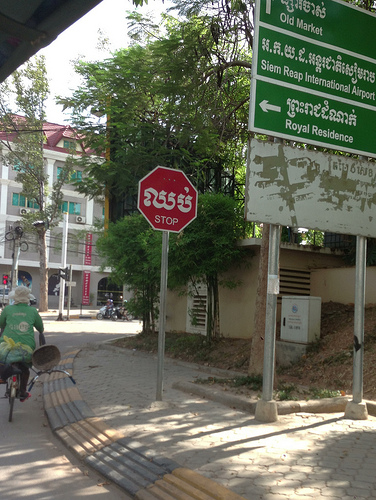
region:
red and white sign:
[119, 155, 194, 225]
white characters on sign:
[128, 167, 202, 230]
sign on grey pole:
[133, 167, 184, 403]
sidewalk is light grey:
[92, 355, 307, 485]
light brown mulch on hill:
[292, 319, 366, 399]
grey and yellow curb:
[43, 348, 201, 497]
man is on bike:
[3, 291, 41, 410]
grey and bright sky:
[29, 8, 121, 116]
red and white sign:
[130, 162, 196, 232]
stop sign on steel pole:
[150, 223, 169, 405]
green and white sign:
[242, 3, 375, 153]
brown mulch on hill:
[314, 295, 375, 382]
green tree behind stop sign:
[94, 8, 245, 305]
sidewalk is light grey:
[92, 331, 356, 493]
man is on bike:
[3, 296, 64, 384]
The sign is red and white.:
[128, 158, 202, 239]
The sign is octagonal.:
[136, 162, 200, 237]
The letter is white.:
[152, 212, 162, 225]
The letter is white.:
[159, 211, 167, 226]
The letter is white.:
[171, 215, 180, 230]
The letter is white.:
[164, 213, 173, 226]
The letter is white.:
[282, 115, 292, 130]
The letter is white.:
[309, 123, 318, 138]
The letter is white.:
[281, 59, 290, 79]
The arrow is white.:
[254, 89, 285, 118]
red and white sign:
[125, 164, 199, 238]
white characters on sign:
[138, 165, 198, 236]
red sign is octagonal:
[138, 165, 189, 233]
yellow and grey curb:
[35, 349, 198, 484]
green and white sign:
[264, 17, 375, 126]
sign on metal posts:
[268, 214, 368, 417]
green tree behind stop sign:
[88, 34, 238, 303]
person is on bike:
[1, 285, 59, 391]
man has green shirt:
[3, 301, 34, 352]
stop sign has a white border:
[137, 163, 198, 233]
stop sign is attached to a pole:
[138, 165, 196, 231]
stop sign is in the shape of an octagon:
[136, 163, 198, 233]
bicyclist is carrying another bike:
[0, 279, 76, 422]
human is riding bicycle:
[1, 284, 46, 421]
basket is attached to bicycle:
[28, 343, 64, 372]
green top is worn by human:
[0, 304, 47, 346]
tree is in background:
[1, 69, 50, 310]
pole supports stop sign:
[157, 227, 168, 401]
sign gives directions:
[246, 74, 375, 157]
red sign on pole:
[129, 148, 193, 413]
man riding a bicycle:
[5, 281, 54, 422]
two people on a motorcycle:
[92, 292, 125, 325]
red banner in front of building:
[76, 231, 99, 316]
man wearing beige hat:
[4, 277, 64, 410]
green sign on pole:
[247, 0, 367, 422]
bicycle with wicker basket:
[26, 328, 77, 403]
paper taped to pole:
[259, 267, 287, 296]